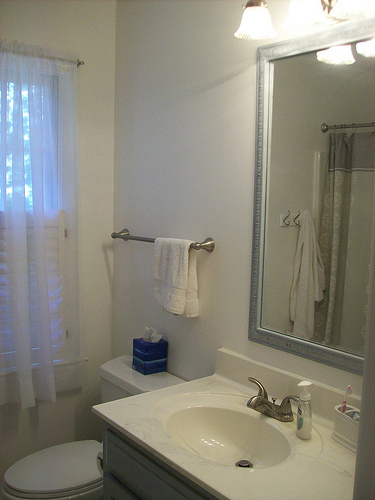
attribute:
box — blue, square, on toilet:
[128, 329, 172, 376]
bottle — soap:
[294, 377, 318, 443]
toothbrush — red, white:
[340, 382, 358, 411]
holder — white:
[334, 406, 363, 452]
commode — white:
[4, 351, 189, 496]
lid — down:
[4, 438, 111, 496]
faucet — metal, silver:
[240, 374, 297, 421]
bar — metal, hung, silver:
[110, 223, 213, 255]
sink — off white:
[93, 347, 358, 500]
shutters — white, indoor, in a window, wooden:
[3, 214, 95, 376]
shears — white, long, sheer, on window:
[1, 39, 89, 418]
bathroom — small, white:
[3, 0, 374, 497]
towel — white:
[149, 236, 200, 319]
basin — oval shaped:
[166, 403, 295, 474]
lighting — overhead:
[232, 0, 373, 43]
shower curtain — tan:
[320, 125, 373, 350]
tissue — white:
[139, 323, 163, 344]